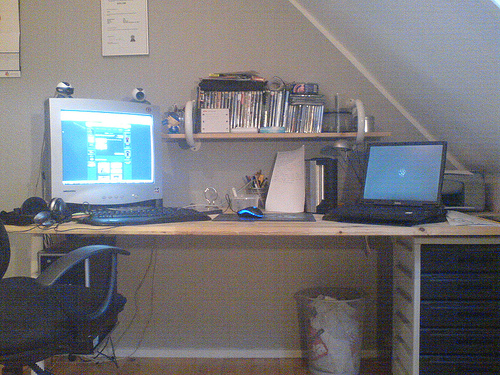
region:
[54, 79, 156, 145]
Two web cams on computer monitor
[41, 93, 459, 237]
Desk with desktop and laptop computers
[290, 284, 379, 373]
Full mesh trash can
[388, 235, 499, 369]
Black and white drawer unit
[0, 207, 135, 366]
Black office chair near desk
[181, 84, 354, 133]
Collection of video games on shelf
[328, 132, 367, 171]
Small silver desk lamp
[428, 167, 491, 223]
Grey computer printer behind laptop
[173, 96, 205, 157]
White metal shelf bracket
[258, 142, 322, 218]
Pieceof white paper leaning against wall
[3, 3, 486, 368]
an office space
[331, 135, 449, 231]
black laptop computer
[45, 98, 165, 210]
desktop computer monitor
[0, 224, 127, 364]
a black office chair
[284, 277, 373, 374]
trash bin on the ground with trash in it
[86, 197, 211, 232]
black keyboard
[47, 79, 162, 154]
webcams on top of monitor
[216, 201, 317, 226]
computer mouse on a pad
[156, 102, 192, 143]
figurine on a shelf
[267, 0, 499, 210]
roof slopes downward on the right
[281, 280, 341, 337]
A trash bin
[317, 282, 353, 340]
A trash bin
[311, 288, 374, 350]
A trash bin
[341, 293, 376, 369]
A trash bin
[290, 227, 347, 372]
A trash bin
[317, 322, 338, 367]
A trash bin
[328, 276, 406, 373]
A trash bin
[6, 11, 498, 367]
a personal office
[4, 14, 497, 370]
a home office area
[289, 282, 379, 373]
a trash can full of papers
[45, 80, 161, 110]
two webcams are on the computer monitor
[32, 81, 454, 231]
two computers are on the desk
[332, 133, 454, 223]
a laptop computer is on the desk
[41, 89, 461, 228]
both computers are powered on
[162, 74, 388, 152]
a shelf above the desk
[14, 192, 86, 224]
headphones are on the desk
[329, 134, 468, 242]
open laptop on desk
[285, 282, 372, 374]
trash can against wall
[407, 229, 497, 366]
stack of drawers under desk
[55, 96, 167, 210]
computer monitor on desk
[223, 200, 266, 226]
computer mouse on pad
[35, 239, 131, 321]
arm of black chair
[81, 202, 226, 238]
black keyboard on desk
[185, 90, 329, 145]
row of disks in cases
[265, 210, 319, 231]
mouse pad on desk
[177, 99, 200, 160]
white curved shelf brace